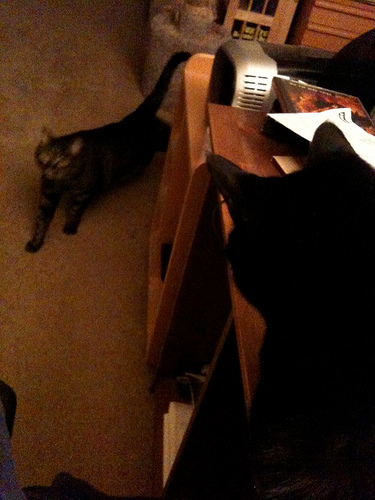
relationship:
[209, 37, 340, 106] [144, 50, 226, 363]
printer on stand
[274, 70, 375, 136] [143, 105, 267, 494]
dvd on furniture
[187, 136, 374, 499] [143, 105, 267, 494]
cat on furniture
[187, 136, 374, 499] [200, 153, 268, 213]
cat has ears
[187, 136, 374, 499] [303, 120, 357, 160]
cat has ears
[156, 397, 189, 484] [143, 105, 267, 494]
documents in furniture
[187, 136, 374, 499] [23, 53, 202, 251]
cat looks at cat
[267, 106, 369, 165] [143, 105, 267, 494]
letter on furniture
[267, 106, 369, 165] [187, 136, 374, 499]
letter by cat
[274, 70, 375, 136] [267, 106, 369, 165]
dvd under letter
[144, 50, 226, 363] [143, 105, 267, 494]
stand by furniture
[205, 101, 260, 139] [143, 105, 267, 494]
ege of furniture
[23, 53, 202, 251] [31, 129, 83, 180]
cat has face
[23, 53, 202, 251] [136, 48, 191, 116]
cat has tail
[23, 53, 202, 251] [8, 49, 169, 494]
cat on carpet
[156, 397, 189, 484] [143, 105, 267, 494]
documents on furniture